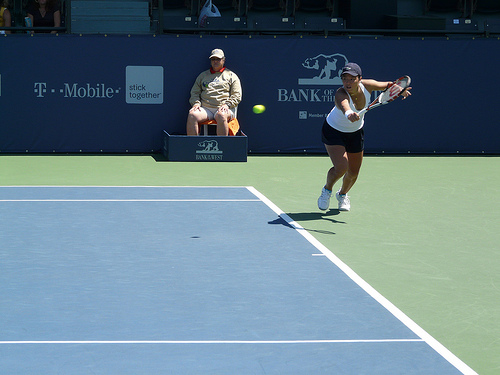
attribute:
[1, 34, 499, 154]
wall — blue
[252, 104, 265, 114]
ball — yellow, green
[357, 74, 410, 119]
racket — white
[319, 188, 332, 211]
shoes — white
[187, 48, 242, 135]
man — sitting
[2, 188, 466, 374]
court — blue, green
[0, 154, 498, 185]
out-of-bounds — green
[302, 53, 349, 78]
bear — image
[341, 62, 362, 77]
hat — blue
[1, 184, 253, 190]
line — white, out of bound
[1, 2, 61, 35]
fans — sitting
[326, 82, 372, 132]
top — white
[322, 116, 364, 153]
shorts — black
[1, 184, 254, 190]
stripe — white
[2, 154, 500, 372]
ground — blue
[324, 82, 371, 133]
shirt — white